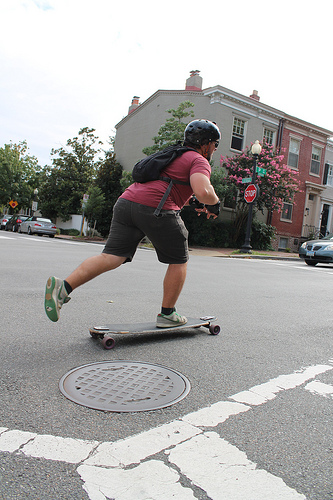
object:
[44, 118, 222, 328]
skateboarder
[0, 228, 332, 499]
road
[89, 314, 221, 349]
skateboard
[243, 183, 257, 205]
stop sign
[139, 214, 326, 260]
corner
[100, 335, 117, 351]
wheel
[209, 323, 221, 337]
wheel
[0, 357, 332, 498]
lines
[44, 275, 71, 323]
shoe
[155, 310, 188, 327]
shoe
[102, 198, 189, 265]
shorts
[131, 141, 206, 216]
backpack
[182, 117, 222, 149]
helmet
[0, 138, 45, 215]
trees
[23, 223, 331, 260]
sidewalk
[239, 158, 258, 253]
light pole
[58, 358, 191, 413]
manhole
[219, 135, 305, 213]
flowers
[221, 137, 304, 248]
tree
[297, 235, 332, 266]
car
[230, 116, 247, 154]
window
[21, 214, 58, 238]
cars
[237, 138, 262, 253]
streetlight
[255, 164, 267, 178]
street signs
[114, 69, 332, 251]
building